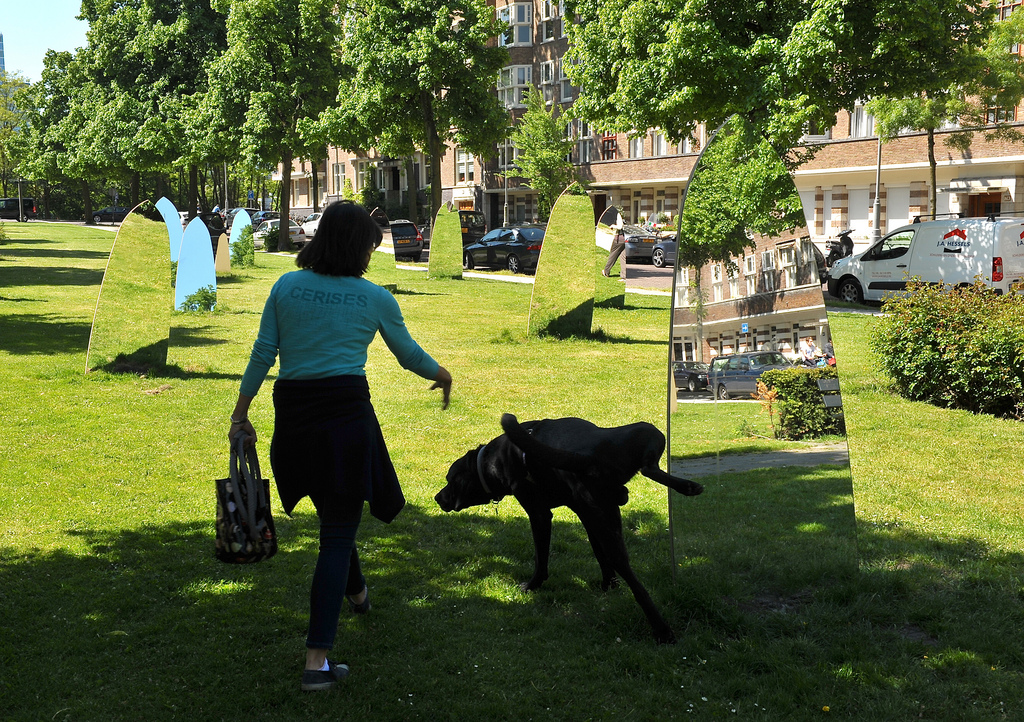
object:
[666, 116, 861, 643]
mirror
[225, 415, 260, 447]
hand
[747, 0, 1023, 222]
tree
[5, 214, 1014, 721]
park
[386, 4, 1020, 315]
curb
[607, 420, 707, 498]
leg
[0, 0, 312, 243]
trees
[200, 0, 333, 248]
leaves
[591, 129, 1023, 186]
shingles brown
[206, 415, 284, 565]
bag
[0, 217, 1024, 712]
ground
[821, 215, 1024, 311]
van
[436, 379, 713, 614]
dog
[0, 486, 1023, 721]
shadow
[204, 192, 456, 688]
woman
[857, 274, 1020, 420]
bush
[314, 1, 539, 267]
tree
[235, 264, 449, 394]
shirt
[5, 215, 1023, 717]
grass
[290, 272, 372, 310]
writing